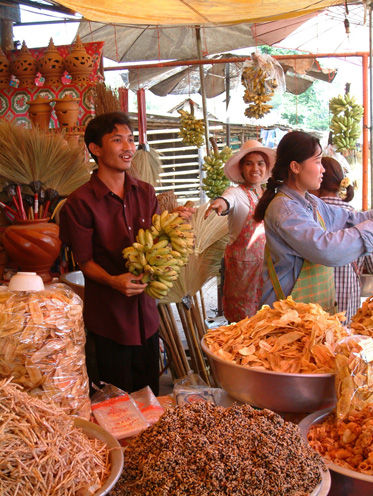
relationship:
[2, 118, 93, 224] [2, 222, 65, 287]
broom inside of pot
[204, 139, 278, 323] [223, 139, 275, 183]
woman has hat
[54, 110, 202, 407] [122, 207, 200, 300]
guy holding bananas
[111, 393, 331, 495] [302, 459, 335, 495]
food piled on platter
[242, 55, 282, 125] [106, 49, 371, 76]
bananas hanging from pole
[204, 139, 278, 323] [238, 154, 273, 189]
woman has head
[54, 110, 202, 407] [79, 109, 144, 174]
guy has head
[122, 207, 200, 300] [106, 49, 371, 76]
bananas hanging from pole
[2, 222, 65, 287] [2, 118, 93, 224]
pot filled with broom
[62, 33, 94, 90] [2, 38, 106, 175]
pot on top of shelf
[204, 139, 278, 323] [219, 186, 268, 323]
woman inside of apron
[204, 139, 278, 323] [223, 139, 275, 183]
woman inside of hat